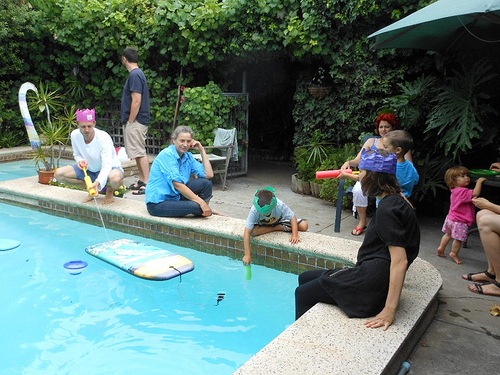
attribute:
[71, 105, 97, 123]
paper hat — pink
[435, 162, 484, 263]
toddler — girl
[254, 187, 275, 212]
crown — green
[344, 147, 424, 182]
hat — paper, purple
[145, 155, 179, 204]
shirt — blue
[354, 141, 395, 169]
hat — blue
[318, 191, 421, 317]
shirt — black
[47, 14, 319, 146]
foliage — lush, green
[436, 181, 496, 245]
girl — little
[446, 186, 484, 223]
shirt — pink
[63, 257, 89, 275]
device — blue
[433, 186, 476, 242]
outfit — pink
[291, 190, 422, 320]
outfit — black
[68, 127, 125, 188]
outfit — white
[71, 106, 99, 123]
party hat — pink, white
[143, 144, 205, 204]
shirt — long sleeve, blue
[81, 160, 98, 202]
gun — squirt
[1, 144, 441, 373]
pool — swimming